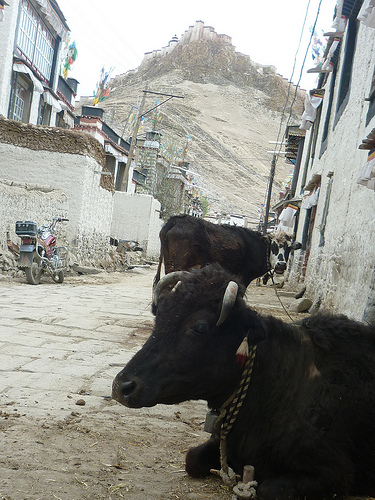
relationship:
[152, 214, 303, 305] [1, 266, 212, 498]
bull on street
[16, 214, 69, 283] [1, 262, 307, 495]
motorcycle parked on street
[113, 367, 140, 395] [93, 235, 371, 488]
nostril on bull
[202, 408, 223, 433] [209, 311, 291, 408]
bell on neck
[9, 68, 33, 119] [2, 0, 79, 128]
window on building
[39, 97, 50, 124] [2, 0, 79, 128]
window on building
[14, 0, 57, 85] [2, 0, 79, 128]
window on building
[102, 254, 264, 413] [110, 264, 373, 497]
head of bull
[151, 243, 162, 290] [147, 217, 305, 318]
tail of cow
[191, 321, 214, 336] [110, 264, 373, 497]
eye of bull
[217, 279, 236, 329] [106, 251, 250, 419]
horn on head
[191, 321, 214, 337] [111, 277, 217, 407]
eye on face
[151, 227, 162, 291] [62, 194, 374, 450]
tail on bulls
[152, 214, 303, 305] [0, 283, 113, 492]
bull laying on ground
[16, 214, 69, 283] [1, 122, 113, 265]
motorcycle near building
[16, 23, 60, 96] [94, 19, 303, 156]
building on hill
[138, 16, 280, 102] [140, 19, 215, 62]
mountain with buildings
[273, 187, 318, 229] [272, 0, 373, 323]
banners hanging off building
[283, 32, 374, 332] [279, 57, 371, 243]
side of building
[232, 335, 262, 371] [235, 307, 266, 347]
tag on cow's ear